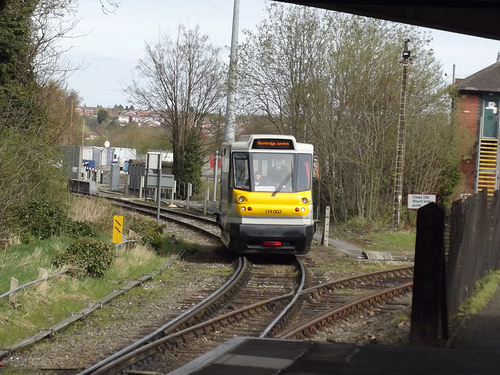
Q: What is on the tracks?
A: The train.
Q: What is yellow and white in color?
A: The train.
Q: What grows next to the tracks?
A: The grass.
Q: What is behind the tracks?
A: The building.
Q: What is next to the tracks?
A: The fence.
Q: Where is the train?
A: On the track.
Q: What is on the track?
A: Train.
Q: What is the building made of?
A: Bricks.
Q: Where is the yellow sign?
A: On the left of the tracks.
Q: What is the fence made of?
A: Wood.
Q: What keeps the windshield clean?
A: The wiper blade.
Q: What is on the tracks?
A: A single train car.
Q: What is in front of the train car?
A: Tracks.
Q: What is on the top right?
A: A building.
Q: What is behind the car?
A: A pole.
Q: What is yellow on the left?
A: A sign.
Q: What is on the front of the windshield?
A: A wiper.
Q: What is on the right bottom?
A: A wooden fence.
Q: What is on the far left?
A: Trees.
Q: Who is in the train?
A: The driver.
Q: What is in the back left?
A: Buildings.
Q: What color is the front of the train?
A: Yellow.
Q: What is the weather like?
A: Sunny.